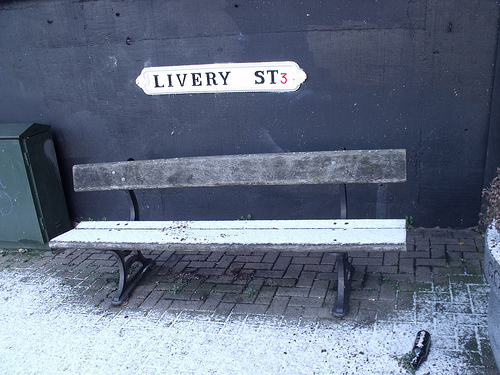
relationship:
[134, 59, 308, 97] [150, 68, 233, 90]
sign with lettering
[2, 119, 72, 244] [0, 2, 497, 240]
trashcan against wall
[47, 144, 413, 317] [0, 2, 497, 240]
bench in front of wall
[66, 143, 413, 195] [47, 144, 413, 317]
backrest of bench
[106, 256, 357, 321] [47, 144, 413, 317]
feet of bench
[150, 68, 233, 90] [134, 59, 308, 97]
lettering on sign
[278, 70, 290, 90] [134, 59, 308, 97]
number on sign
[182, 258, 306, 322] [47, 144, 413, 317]
bricks under bench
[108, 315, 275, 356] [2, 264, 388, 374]
paint on bricks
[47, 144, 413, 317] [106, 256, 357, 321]
bench with feet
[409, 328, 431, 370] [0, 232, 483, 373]
bottle on ground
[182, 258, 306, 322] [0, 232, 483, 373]
bricks on ground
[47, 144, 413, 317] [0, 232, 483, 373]
bench on ground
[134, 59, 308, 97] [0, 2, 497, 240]
sign on wall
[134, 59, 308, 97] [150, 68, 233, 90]
sign has lettering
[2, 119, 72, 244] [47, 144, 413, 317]
trashcan on side of bench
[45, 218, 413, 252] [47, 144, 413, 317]
seat of bench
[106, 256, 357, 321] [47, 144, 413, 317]
feet on bench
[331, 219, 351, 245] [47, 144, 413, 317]
screws hold bench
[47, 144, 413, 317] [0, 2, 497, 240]
bench next to wall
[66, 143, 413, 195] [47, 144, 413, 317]
backrest on bench